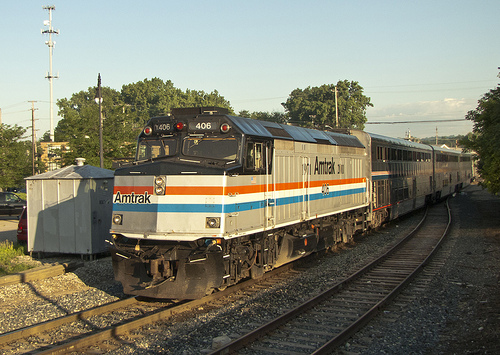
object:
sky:
[0, 0, 499, 145]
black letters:
[114, 190, 152, 203]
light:
[154, 177, 164, 186]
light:
[154, 186, 164, 195]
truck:
[0, 190, 25, 215]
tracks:
[204, 198, 451, 355]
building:
[22, 157, 115, 261]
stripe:
[200, 176, 368, 213]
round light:
[143, 125, 152, 136]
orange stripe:
[112, 185, 224, 195]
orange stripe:
[224, 177, 366, 196]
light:
[219, 121, 232, 134]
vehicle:
[15, 207, 33, 245]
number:
[195, 121, 212, 130]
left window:
[140, 139, 178, 160]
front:
[103, 105, 243, 302]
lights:
[38, 3, 59, 142]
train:
[104, 106, 479, 305]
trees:
[35, 77, 375, 173]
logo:
[312, 155, 335, 174]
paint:
[238, 136, 274, 176]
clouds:
[426, 100, 465, 112]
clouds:
[369, 100, 417, 120]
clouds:
[290, 42, 348, 62]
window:
[241, 137, 271, 175]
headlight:
[112, 214, 124, 225]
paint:
[184, 186, 223, 195]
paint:
[203, 193, 219, 205]